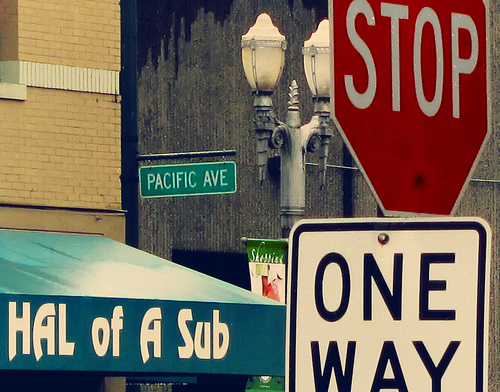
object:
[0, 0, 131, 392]
building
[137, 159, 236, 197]
banner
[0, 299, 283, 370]
banner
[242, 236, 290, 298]
posta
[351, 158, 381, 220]
pole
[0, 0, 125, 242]
brick wall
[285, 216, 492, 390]
sign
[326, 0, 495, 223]
stop sign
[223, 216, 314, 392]
green banner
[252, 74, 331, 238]
lamp post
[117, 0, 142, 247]
pole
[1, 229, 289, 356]
awning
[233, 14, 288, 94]
bulb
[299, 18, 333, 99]
bulb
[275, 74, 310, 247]
pole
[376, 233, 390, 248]
bolt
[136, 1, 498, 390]
building